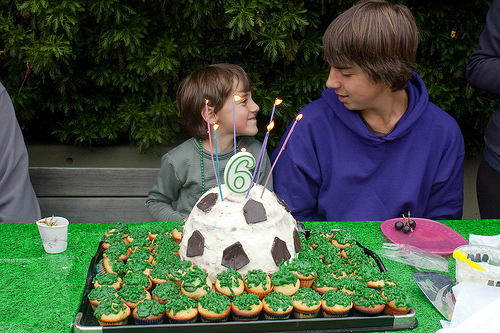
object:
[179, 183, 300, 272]
cake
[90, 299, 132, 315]
cupcakes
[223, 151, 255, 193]
number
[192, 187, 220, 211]
candles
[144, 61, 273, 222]
boy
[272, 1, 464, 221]
boy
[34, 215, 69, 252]
cup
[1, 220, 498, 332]
table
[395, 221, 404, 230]
fruit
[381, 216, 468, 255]
plate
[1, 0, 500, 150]
tree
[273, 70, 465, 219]
clothing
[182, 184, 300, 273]
frosting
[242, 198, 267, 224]
candle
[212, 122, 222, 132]
flames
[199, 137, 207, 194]
necklace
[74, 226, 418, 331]
tray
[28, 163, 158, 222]
bench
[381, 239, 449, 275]
bag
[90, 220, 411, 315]
frosting